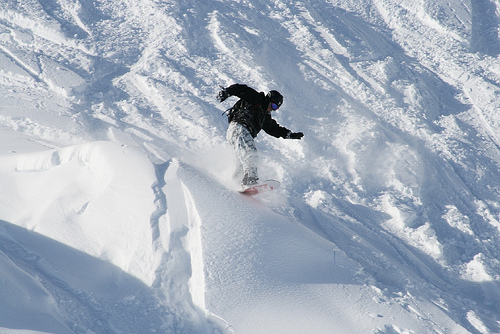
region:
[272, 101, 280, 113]
reflective goggles on snowboarder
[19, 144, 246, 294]
large mound of white snow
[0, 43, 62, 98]
tracks in snow made by skier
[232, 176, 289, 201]
red and white snowboard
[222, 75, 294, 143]
snowboarder in black jacket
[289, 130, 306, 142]
black glove on left hand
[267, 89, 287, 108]
snowboarder has hat on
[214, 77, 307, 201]
snowboarder going down hill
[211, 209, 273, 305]
undisturbed patch of snow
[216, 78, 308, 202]
snowboarder with arms out for balance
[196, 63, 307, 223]
person snowboarding down the slope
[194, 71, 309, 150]
black long sleeved jacket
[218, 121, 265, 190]
light colored snow pants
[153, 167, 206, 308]
tracks in the snow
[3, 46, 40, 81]
skinny track in the snow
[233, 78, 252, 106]
elbow bent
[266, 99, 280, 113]
snow goggles that are tinted blue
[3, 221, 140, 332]
shadow on the ground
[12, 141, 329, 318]
small mound of snow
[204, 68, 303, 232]
The snowboarder is wearing a black jacket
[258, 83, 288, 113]
The person is wearing blue goggles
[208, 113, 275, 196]
The pants are checkered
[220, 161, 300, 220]
The snowboard is red and white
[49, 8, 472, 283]
The mountain is steep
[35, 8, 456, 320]
The mountain is covered in snow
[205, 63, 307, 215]
The person rides off a jump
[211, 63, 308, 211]
The person is snowboarding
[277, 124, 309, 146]
The person is wearing black gloves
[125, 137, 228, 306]
There are tracks in the snow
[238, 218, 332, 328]
the snow is white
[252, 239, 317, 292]
the snow is white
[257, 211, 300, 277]
the snow is white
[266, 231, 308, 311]
the snow is white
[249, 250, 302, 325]
the snow is white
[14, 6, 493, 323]
a snowboarder on a steep slope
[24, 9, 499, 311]
the powder snow is plentiful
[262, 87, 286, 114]
the snowboarder has a helmet on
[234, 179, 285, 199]
the snowboard is white and red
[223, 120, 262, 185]
the pants are heavily dusted with snow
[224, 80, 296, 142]
a down jacket is on the boy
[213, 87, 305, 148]
the boy is wearing ski gloves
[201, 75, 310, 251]
the snowboarder is going over a snow mound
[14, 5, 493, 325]
shadows are around the snow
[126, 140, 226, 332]
tracks from a previous board